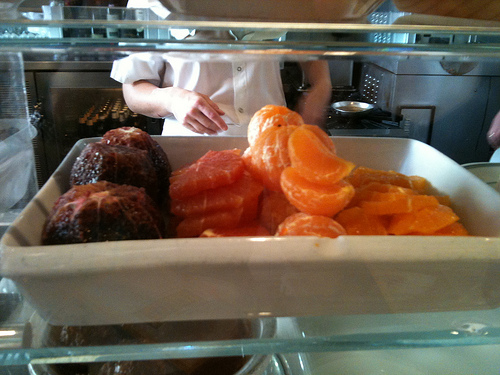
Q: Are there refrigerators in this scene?
A: Yes, there is a refrigerator.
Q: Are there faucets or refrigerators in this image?
A: Yes, there is a refrigerator.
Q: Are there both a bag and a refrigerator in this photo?
A: Yes, there are both a refrigerator and a bag.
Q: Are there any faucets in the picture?
A: No, there are no faucets.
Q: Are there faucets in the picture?
A: No, there are no faucets.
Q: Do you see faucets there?
A: No, there are no faucets.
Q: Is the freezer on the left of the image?
A: Yes, the freezer is on the left of the image.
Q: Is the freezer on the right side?
A: No, the freezer is on the left of the image.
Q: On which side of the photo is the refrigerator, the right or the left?
A: The refrigerator is on the left of the image.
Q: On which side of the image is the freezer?
A: The freezer is on the left of the image.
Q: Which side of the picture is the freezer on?
A: The freezer is on the left of the image.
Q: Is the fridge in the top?
A: Yes, the fridge is in the top of the image.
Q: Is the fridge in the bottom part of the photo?
A: No, the fridge is in the top of the image.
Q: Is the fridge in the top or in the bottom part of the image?
A: The fridge is in the top of the image.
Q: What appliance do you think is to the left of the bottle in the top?
A: The appliance is a refrigerator.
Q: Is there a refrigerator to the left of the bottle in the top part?
A: Yes, there is a refrigerator to the left of the bottle.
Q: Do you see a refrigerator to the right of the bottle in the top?
A: No, the refrigerator is to the left of the bottle.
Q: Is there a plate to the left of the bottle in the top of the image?
A: No, there is a refrigerator to the left of the bottle.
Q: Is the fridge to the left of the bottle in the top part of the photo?
A: Yes, the fridge is to the left of the bottle.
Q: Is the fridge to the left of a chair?
A: No, the fridge is to the left of the bottle.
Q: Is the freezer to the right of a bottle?
A: No, the freezer is to the left of a bottle.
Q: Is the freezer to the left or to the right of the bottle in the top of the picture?
A: The freezer is to the left of the bottle.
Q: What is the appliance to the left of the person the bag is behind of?
A: The appliance is a refrigerator.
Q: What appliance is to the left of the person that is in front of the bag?
A: The appliance is a refrigerator.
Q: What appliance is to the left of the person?
A: The appliance is a refrigerator.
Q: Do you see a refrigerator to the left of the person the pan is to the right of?
A: Yes, there is a refrigerator to the left of the person.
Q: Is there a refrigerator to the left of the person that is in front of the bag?
A: Yes, there is a refrigerator to the left of the person.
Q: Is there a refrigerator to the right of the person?
A: No, the refrigerator is to the left of the person.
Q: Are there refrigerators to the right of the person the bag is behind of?
A: No, the refrigerator is to the left of the person.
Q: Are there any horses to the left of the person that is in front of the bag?
A: No, there is a refrigerator to the left of the person.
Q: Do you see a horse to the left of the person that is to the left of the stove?
A: No, there is a refrigerator to the left of the person.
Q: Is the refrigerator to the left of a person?
A: Yes, the refrigerator is to the left of a person.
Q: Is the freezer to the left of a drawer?
A: No, the freezer is to the left of a person.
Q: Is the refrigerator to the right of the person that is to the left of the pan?
A: No, the refrigerator is to the left of the person.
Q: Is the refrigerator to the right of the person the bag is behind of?
A: No, the refrigerator is to the left of the person.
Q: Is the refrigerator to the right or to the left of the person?
A: The refrigerator is to the left of the person.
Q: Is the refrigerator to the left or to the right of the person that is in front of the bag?
A: The refrigerator is to the left of the person.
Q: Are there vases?
A: No, there are no vases.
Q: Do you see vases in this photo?
A: No, there are no vases.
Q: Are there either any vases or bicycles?
A: No, there are no vases or bicycles.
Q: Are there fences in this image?
A: No, there are no fences.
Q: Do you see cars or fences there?
A: No, there are no fences or cars.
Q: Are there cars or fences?
A: No, there are no fences or cars.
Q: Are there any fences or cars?
A: No, there are no fences or cars.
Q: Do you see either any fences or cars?
A: No, there are no fences or cars.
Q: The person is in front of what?
A: The person is in front of the bag.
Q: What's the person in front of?
A: The person is in front of the bag.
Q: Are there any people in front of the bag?
A: Yes, there is a person in front of the bag.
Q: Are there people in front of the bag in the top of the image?
A: Yes, there is a person in front of the bag.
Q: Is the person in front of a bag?
A: Yes, the person is in front of a bag.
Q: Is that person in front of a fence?
A: No, the person is in front of a bag.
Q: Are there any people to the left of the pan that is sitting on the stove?
A: Yes, there is a person to the left of the pan.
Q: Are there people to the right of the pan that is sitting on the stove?
A: No, the person is to the left of the pan.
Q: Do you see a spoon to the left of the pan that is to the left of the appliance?
A: No, there is a person to the left of the pan.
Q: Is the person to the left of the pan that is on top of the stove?
A: Yes, the person is to the left of the pan.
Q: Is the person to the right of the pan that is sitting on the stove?
A: No, the person is to the left of the pan.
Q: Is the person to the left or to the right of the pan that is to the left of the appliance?
A: The person is to the left of the pan.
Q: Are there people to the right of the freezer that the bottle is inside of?
A: Yes, there is a person to the right of the fridge.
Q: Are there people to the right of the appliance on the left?
A: Yes, there is a person to the right of the fridge.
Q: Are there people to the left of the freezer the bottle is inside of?
A: No, the person is to the right of the freezer.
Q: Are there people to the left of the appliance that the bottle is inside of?
A: No, the person is to the right of the freezer.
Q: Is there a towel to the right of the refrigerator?
A: No, there is a person to the right of the refrigerator.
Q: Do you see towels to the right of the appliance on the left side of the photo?
A: No, there is a person to the right of the refrigerator.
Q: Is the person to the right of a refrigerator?
A: Yes, the person is to the right of a refrigerator.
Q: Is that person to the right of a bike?
A: No, the person is to the right of a refrigerator.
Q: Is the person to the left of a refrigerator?
A: No, the person is to the right of a refrigerator.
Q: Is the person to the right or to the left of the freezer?
A: The person is to the right of the freezer.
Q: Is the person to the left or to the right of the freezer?
A: The person is to the right of the freezer.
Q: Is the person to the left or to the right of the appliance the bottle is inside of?
A: The person is to the right of the freezer.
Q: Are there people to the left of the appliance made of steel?
A: Yes, there is a person to the left of the appliance.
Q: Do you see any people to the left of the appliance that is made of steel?
A: Yes, there is a person to the left of the appliance.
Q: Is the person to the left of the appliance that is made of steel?
A: Yes, the person is to the left of the appliance.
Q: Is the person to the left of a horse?
A: No, the person is to the left of the appliance.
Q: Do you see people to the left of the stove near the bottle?
A: Yes, there is a person to the left of the stove.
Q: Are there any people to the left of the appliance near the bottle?
A: Yes, there is a person to the left of the stove.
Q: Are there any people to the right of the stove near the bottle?
A: No, the person is to the left of the stove.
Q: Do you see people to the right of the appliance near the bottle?
A: No, the person is to the left of the stove.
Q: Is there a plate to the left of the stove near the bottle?
A: No, there is a person to the left of the stove.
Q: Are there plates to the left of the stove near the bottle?
A: No, there is a person to the left of the stove.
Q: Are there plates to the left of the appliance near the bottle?
A: No, there is a person to the left of the stove.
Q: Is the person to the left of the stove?
A: Yes, the person is to the left of the stove.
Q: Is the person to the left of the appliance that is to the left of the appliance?
A: Yes, the person is to the left of the stove.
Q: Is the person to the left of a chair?
A: No, the person is to the left of the stove.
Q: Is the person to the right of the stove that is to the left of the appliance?
A: No, the person is to the left of the stove.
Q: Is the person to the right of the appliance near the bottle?
A: No, the person is to the left of the stove.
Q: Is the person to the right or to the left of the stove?
A: The person is to the left of the stove.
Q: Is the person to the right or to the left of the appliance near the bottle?
A: The person is to the left of the stove.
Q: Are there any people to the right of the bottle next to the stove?
A: Yes, there is a person to the right of the bottle.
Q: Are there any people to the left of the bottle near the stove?
A: No, the person is to the right of the bottle.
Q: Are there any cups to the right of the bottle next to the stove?
A: No, there is a person to the right of the bottle.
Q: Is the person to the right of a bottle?
A: Yes, the person is to the right of a bottle.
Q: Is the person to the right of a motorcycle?
A: No, the person is to the right of a bottle.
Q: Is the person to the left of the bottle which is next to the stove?
A: No, the person is to the right of the bottle.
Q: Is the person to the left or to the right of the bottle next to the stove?
A: The person is to the right of the bottle.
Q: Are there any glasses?
A: No, there are no glasses.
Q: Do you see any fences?
A: No, there are no fences.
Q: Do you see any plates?
A: No, there are no plates.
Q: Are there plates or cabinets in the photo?
A: No, there are no plates or cabinets.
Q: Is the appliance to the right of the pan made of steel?
A: Yes, the appliance is made of steel.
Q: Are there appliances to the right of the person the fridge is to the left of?
A: Yes, there is an appliance to the right of the person.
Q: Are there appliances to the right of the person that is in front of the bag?
A: Yes, there is an appliance to the right of the person.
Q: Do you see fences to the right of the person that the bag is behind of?
A: No, there is an appliance to the right of the person.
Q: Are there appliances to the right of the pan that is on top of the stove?
A: Yes, there is an appliance to the right of the pan.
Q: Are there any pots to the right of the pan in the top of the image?
A: No, there is an appliance to the right of the pan.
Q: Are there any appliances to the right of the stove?
A: Yes, there is an appliance to the right of the stove.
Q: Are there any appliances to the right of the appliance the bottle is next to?
A: Yes, there is an appliance to the right of the stove.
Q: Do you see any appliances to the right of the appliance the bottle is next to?
A: Yes, there is an appliance to the right of the stove.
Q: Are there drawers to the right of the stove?
A: No, there is an appliance to the right of the stove.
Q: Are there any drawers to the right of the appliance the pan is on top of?
A: No, there is an appliance to the right of the stove.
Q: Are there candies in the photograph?
A: No, there are no candies.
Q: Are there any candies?
A: No, there are no candies.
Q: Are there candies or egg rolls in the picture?
A: No, there are no candies or egg rolls.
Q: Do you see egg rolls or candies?
A: No, there are no candies or egg rolls.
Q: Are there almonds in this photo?
A: No, there are no almonds.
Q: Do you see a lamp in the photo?
A: No, there are no lamps.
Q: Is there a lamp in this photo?
A: No, there are no lamps.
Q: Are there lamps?
A: No, there are no lamps.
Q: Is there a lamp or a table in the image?
A: No, there are no lamps or tables.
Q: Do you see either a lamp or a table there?
A: No, there are no lamps or tables.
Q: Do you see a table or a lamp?
A: No, there are no lamps or tables.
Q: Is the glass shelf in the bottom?
A: Yes, the shelf is in the bottom of the image.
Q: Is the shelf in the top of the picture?
A: No, the shelf is in the bottom of the image.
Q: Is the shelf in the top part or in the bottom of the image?
A: The shelf is in the bottom of the image.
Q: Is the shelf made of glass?
A: Yes, the shelf is made of glass.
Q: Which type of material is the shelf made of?
A: The shelf is made of glass.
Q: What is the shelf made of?
A: The shelf is made of glass.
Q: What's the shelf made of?
A: The shelf is made of glass.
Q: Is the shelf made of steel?
A: No, the shelf is made of glass.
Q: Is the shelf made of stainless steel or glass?
A: The shelf is made of glass.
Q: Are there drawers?
A: No, there are no drawers.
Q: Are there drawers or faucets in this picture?
A: No, there are no drawers or faucets.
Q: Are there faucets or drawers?
A: No, there are no drawers or faucets.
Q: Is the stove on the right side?
A: Yes, the stove is on the right of the image.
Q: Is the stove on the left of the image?
A: No, the stove is on the right of the image.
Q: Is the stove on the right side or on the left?
A: The stove is on the right of the image.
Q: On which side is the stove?
A: The stove is on the right of the image.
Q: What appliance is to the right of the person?
A: The appliance is a stove.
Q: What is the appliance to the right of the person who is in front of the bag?
A: The appliance is a stove.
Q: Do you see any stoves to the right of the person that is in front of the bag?
A: Yes, there is a stove to the right of the person.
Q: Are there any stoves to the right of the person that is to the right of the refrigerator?
A: Yes, there is a stove to the right of the person.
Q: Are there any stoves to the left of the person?
A: No, the stove is to the right of the person.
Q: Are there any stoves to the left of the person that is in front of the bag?
A: No, the stove is to the right of the person.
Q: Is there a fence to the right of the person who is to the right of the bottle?
A: No, there is a stove to the right of the person.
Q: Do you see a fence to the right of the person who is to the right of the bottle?
A: No, there is a stove to the right of the person.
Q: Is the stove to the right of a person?
A: Yes, the stove is to the right of a person.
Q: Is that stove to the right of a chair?
A: No, the stove is to the right of a person.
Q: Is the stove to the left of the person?
A: No, the stove is to the right of the person.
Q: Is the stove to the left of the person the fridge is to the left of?
A: No, the stove is to the right of the person.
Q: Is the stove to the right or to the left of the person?
A: The stove is to the right of the person.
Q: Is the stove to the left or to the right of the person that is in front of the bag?
A: The stove is to the right of the person.